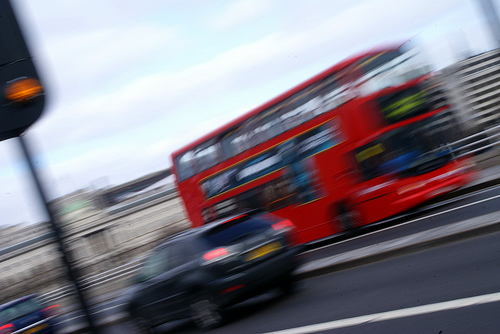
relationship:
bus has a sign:
[172, 44, 475, 246] [198, 118, 348, 203]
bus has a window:
[172, 44, 475, 246] [346, 49, 427, 92]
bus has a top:
[172, 44, 475, 246] [171, 45, 430, 180]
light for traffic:
[0, 1, 45, 141] [129, 46, 476, 330]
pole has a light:
[19, 136, 101, 333] [0, 1, 45, 141]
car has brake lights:
[122, 208, 299, 333] [271, 219, 294, 232]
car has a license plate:
[122, 208, 299, 333] [247, 241, 281, 262]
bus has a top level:
[172, 44, 475, 246] [172, 43, 428, 180]